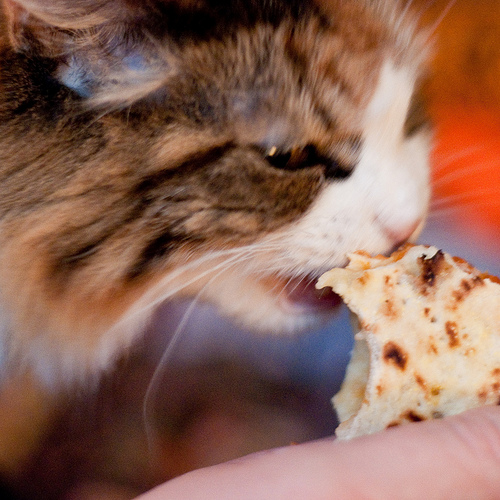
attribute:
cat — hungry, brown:
[1, 0, 434, 397]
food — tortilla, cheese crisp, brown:
[315, 240, 499, 441]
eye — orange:
[249, 140, 322, 173]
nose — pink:
[376, 217, 424, 246]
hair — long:
[74, 82, 162, 131]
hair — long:
[16, 0, 121, 31]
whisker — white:
[141, 252, 265, 463]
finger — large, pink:
[319, 403, 500, 499]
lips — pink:
[273, 277, 344, 315]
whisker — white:
[100, 216, 339, 339]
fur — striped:
[2, 0, 434, 382]